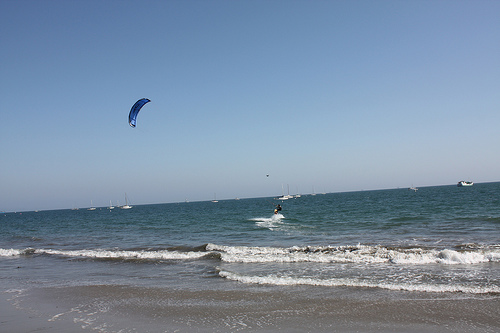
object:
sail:
[127, 97, 152, 129]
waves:
[1, 243, 500, 294]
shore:
[0, 277, 500, 333]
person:
[272, 203, 282, 215]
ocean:
[0, 179, 500, 333]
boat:
[456, 180, 474, 188]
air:
[1, 1, 500, 214]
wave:
[246, 211, 287, 232]